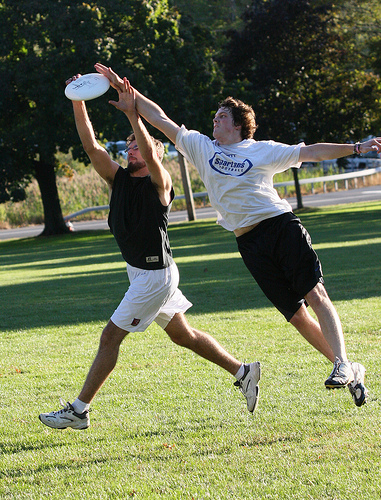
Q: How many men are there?
A: 2.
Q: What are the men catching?
A: Frisbee.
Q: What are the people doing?
A: Playing frisbee.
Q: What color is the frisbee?
A: White.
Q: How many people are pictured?
A: Two.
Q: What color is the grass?
A: Green.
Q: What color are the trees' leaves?
A: Green.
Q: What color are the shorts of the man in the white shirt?
A: Black.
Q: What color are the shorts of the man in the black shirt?
A: White.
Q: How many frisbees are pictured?
A: One.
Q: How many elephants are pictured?
A: Zero.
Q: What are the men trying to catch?
A: A frisbee.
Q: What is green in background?
A: Large leaves on trees.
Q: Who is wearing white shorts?
A: Man in black shirt.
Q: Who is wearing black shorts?
A: Man in white shirt with blue logo.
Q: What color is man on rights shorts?
A: Black.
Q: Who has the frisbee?
A: Jumping man on left.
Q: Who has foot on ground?
A: Man on left with tennis shoes.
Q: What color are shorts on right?
A: Black.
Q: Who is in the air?
A: The man.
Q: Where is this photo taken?
A: On a grassy field.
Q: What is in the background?
A: Trees.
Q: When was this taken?
A: Daytime.